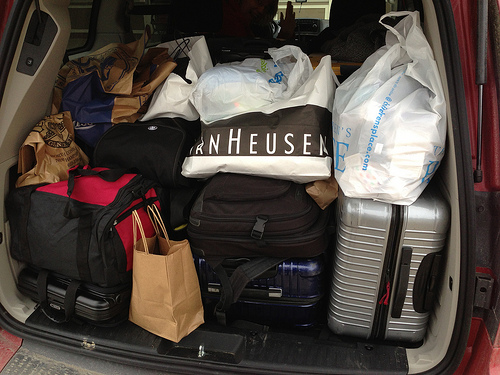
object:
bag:
[334, 9, 448, 207]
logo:
[43, 122, 74, 148]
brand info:
[188, 127, 333, 156]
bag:
[180, 44, 339, 185]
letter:
[331, 139, 348, 173]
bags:
[49, 23, 177, 126]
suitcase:
[327, 189, 451, 350]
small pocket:
[201, 173, 291, 202]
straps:
[204, 257, 289, 327]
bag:
[184, 172, 330, 260]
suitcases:
[88, 119, 201, 186]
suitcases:
[12, 262, 133, 328]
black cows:
[327, 0, 383, 66]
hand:
[278, 3, 300, 40]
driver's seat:
[196, 0, 282, 68]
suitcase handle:
[390, 247, 413, 318]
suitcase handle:
[206, 282, 282, 299]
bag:
[127, 203, 205, 344]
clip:
[250, 215, 270, 241]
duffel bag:
[4, 165, 163, 289]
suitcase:
[184, 257, 327, 332]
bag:
[12, 111, 90, 189]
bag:
[188, 45, 314, 124]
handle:
[128, 207, 149, 254]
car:
[0, 0, 499, 375]